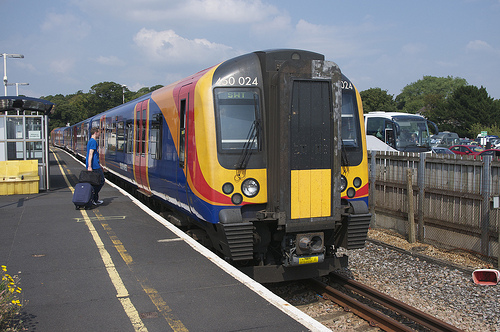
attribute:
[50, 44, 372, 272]
commuter train — busy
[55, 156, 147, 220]
bags — blue, black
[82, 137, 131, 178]
shirt — blue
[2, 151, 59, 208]
wall — yellow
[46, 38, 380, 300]
train — 50 024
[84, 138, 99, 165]
shirt — blue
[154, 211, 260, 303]
line — white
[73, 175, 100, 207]
suit case — blue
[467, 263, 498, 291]
cone — orange